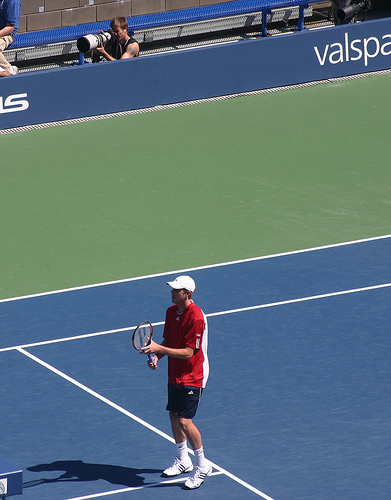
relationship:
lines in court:
[112, 44, 336, 366] [21, 36, 389, 362]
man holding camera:
[132, 273, 212, 490] [72, 29, 115, 54]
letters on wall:
[315, 19, 358, 74] [85, 33, 378, 114]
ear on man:
[183, 287, 195, 298] [132, 273, 212, 490]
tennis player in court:
[134, 245, 226, 499] [5, 474, 378, 494]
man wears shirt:
[132, 273, 212, 490] [131, 262, 220, 392]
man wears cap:
[132, 273, 212, 490] [164, 276, 196, 289]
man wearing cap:
[132, 273, 212, 490] [164, 275, 195, 291]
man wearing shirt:
[132, 273, 212, 490] [162, 298, 207, 387]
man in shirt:
[132, 273, 212, 490] [160, 300, 211, 387]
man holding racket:
[132, 273, 212, 490] [130, 318, 157, 368]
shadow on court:
[10, 456, 168, 490] [3, 194, 378, 496]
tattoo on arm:
[164, 346, 190, 362] [122, 320, 203, 360]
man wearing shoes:
[132, 273, 212, 490] [156, 461, 214, 489]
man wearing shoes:
[132, 273, 212, 490] [162, 458, 194, 474]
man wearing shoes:
[132, 273, 212, 490] [160, 449, 216, 491]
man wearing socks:
[132, 273, 212, 490] [173, 439, 189, 457]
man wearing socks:
[132, 273, 212, 490] [193, 446, 205, 465]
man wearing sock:
[132, 273, 212, 490] [192, 445, 208, 466]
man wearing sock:
[132, 273, 212, 490] [174, 440, 188, 458]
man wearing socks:
[132, 273, 212, 490] [143, 430, 234, 467]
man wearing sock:
[132, 273, 212, 490] [176, 440, 187, 462]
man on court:
[132, 273, 212, 490] [4, 108, 375, 495]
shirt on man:
[156, 297, 214, 389] [160, 271, 216, 491]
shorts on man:
[140, 385, 196, 412] [102, 251, 231, 497]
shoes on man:
[150, 441, 230, 497] [102, 251, 251, 424]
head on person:
[169, 275, 198, 303] [135, 274, 210, 487]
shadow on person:
[10, 456, 168, 490] [140, 274, 213, 489]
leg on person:
[180, 418, 208, 468] [140, 274, 213, 489]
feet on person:
[165, 453, 214, 492] [149, 271, 213, 487]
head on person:
[169, 275, 198, 303] [94, 17, 140, 58]